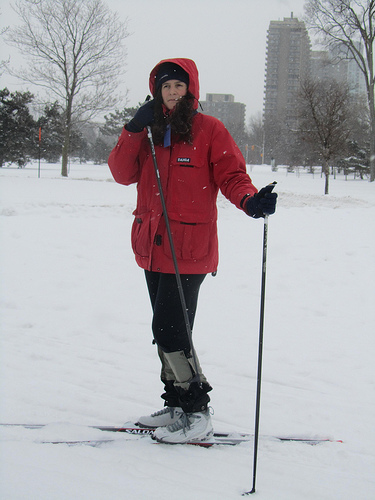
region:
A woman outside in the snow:
[101, 44, 285, 487]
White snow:
[0, 157, 372, 498]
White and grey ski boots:
[135, 400, 217, 445]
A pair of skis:
[7, 413, 352, 462]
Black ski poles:
[136, 94, 282, 496]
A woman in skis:
[7, 50, 354, 471]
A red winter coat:
[106, 54, 262, 275]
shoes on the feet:
[136, 408, 230, 444]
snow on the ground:
[36, 453, 114, 490]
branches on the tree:
[25, 20, 104, 84]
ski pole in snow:
[237, 463, 267, 492]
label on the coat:
[173, 153, 198, 164]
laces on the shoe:
[162, 422, 194, 434]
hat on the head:
[155, 68, 186, 83]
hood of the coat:
[142, 50, 203, 76]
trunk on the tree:
[57, 155, 71, 178]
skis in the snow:
[98, 423, 129, 434]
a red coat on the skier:
[95, 44, 308, 279]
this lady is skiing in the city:
[112, 63, 307, 329]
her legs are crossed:
[124, 261, 232, 472]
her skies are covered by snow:
[6, 397, 352, 468]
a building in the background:
[259, 10, 361, 175]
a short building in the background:
[204, 81, 252, 163]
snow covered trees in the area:
[6, 80, 96, 172]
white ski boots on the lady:
[118, 396, 234, 462]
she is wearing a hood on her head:
[137, 49, 205, 114]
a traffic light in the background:
[240, 129, 270, 163]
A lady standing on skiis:
[96, 41, 285, 499]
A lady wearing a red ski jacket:
[95, 46, 270, 289]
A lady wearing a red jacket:
[110, 51, 273, 284]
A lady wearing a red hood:
[126, 54, 211, 117]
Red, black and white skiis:
[26, 393, 344, 453]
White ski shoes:
[136, 394, 217, 445]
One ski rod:
[227, 218, 282, 496]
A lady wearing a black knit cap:
[141, 48, 205, 105]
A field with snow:
[287, 108, 372, 350]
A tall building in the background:
[258, 6, 312, 178]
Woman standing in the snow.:
[101, 48, 285, 498]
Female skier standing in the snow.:
[97, 50, 287, 498]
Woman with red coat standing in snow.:
[95, 49, 279, 498]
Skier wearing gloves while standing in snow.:
[99, 52, 279, 498]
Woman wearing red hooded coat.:
[97, 49, 279, 498]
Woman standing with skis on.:
[99, 48, 281, 498]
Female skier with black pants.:
[99, 50, 280, 497]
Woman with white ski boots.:
[93, 51, 280, 497]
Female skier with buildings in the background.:
[0, 0, 373, 498]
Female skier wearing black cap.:
[99, 50, 283, 496]